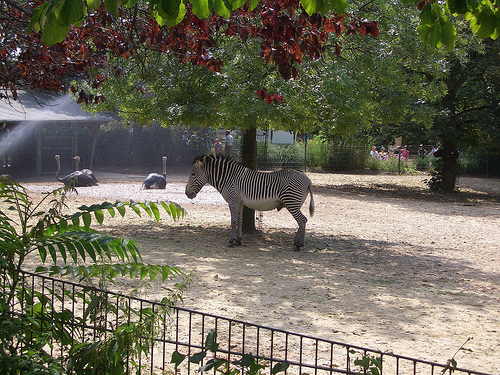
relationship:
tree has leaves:
[240, 122, 260, 235] [74, 2, 408, 143]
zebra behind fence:
[183, 152, 315, 251] [6, 264, 478, 374]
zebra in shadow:
[183, 152, 315, 251] [39, 222, 487, 347]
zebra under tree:
[183, 152, 315, 251] [240, 122, 260, 235]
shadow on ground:
[39, 222, 487, 347] [1, 173, 499, 372]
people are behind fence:
[370, 143, 441, 158] [174, 133, 442, 175]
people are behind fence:
[183, 128, 238, 157] [174, 133, 442, 175]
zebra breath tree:
[183, 152, 315, 251] [240, 122, 260, 235]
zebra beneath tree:
[183, 152, 315, 251] [240, 122, 260, 235]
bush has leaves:
[4, 187, 25, 355] [3, 176, 184, 369]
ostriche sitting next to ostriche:
[52, 154, 98, 187] [72, 155, 82, 169]